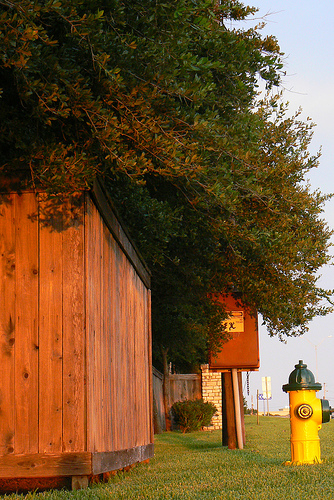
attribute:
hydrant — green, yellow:
[285, 355, 325, 473]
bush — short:
[170, 399, 225, 433]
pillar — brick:
[205, 366, 217, 400]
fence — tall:
[93, 226, 117, 434]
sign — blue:
[258, 391, 263, 402]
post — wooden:
[226, 385, 232, 447]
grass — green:
[165, 456, 269, 498]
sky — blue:
[289, 14, 323, 69]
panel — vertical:
[72, 243, 82, 436]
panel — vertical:
[140, 292, 152, 440]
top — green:
[294, 364, 312, 385]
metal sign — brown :
[206, 281, 259, 371]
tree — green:
[6, 2, 325, 402]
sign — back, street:
[209, 293, 283, 461]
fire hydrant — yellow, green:
[281, 358, 333, 465]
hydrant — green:
[276, 361, 331, 463]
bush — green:
[166, 397, 218, 438]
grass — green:
[4, 415, 329, 498]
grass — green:
[153, 430, 287, 496]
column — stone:
[198, 359, 225, 431]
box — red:
[192, 277, 273, 466]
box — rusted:
[201, 278, 260, 372]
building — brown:
[1, 161, 157, 487]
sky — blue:
[287, 9, 329, 66]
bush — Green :
[169, 398, 211, 433]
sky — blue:
[230, 18, 326, 440]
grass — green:
[188, 446, 243, 480]